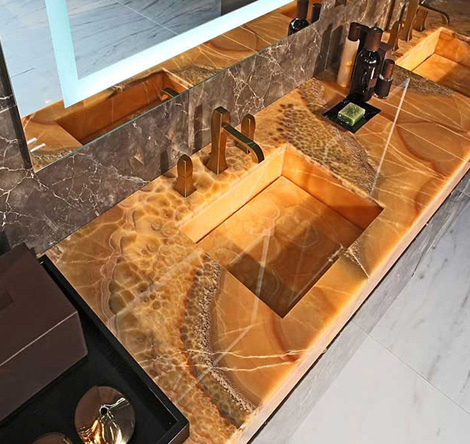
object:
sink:
[392, 24, 470, 99]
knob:
[172, 154, 196, 198]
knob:
[236, 114, 256, 155]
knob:
[387, 21, 402, 53]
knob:
[414, 3, 428, 32]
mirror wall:
[0, 0, 419, 256]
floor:
[245, 167, 470, 444]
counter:
[35, 0, 470, 444]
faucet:
[204, 105, 264, 175]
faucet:
[396, 0, 449, 42]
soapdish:
[323, 95, 382, 135]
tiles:
[347, 187, 470, 419]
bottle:
[347, 26, 382, 102]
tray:
[0, 252, 193, 444]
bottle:
[336, 20, 360, 89]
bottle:
[374, 58, 395, 98]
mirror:
[0, 0, 356, 176]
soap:
[337, 102, 366, 127]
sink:
[178, 138, 387, 315]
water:
[251, 151, 265, 163]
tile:
[248, 317, 467, 444]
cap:
[348, 22, 363, 41]